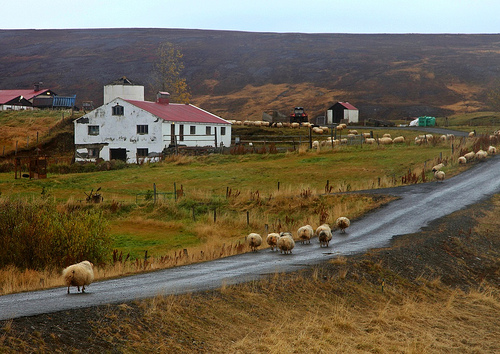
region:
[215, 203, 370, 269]
several sheep standing in a road way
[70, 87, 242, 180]
a white barn with a red roof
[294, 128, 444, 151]
several sheep in a field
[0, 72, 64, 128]
two buildings with red roofs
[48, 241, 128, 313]
a sheep walking in a road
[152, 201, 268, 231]
wood fence post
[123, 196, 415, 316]
a paved road way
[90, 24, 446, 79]
a tall hill side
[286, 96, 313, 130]
a large tractor next to a barn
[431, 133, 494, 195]
sheep eating grass next to a road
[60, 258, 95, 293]
A hairy sheep way behind the rest.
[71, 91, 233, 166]
A large white and red barn beside a silo.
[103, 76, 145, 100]
A tall white silo with metal on the top.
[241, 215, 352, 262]
The sheep in the middle road.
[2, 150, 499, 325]
The wet grey road that sheep are on.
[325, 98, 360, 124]
A tall white barn with a red roof and giant black area.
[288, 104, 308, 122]
A very large black tractor with it's red tail lights on.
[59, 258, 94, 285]
The fur on the last sheep on the road.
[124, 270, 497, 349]
All the brown grass on this side of the road.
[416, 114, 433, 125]
A green container way up the road.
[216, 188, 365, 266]
bunch of lamps walking on street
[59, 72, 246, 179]
a large warehouse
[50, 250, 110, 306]
lamp walking on street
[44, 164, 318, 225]
a plain old field of grass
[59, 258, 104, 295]
a sheep with fur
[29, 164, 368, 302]
sheep walking on street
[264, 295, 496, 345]
dry grass on field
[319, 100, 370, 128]
a warehouse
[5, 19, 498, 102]
the mountain fields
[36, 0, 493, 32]
blue sky with no clouds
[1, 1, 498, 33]
pale blue of sky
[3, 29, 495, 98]
land on horizon under sky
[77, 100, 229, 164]
white and red barn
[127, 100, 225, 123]
slanted red roof on barn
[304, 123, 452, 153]
herd of sheep on grass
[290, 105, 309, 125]
tractor with glowing lights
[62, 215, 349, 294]
sheep walking on road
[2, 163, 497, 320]
paved road next to farm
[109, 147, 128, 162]
open door on barn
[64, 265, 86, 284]
back of walking sheep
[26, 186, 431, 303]
sheeps are walking on a road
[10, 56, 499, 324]
many sheeps on a field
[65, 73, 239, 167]
the home is color white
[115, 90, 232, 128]
the roof of home is color red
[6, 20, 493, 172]
a mountain on the background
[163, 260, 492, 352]
the grass is dry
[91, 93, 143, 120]
a window on top a home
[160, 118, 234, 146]
a door on side a home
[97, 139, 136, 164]
the front door of home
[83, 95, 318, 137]
a car behind a home